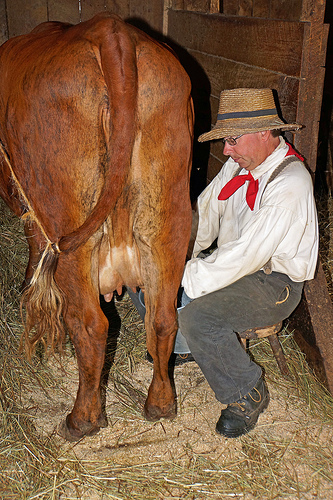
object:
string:
[16, 232, 69, 353]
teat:
[103, 290, 113, 305]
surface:
[149, 249, 184, 293]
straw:
[53, 432, 164, 497]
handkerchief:
[216, 158, 258, 211]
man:
[177, 87, 319, 438]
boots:
[147, 341, 274, 436]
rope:
[18, 17, 138, 370]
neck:
[245, 135, 283, 171]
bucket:
[129, 287, 194, 353]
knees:
[143, 301, 180, 360]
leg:
[44, 243, 108, 444]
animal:
[0, 11, 196, 444]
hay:
[0, 169, 331, 497]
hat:
[197, 86, 304, 143]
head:
[198, 85, 304, 171]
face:
[223, 131, 268, 171]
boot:
[215, 374, 270, 438]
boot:
[146, 348, 194, 366]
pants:
[125, 247, 304, 405]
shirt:
[181, 135, 321, 298]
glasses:
[222, 133, 239, 145]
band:
[215, 104, 280, 118]